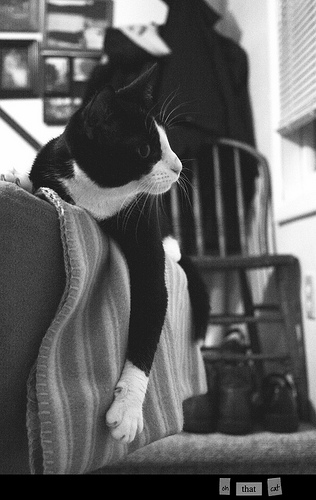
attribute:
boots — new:
[212, 356, 299, 436]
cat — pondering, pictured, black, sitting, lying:
[30, 62, 212, 443]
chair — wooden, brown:
[169, 139, 309, 419]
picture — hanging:
[38, 48, 100, 124]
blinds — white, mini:
[274, 5, 314, 133]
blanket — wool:
[24, 188, 210, 475]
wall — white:
[223, 1, 314, 431]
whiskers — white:
[133, 88, 180, 223]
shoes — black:
[218, 363, 298, 435]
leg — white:
[158, 237, 183, 262]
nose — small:
[165, 156, 183, 173]